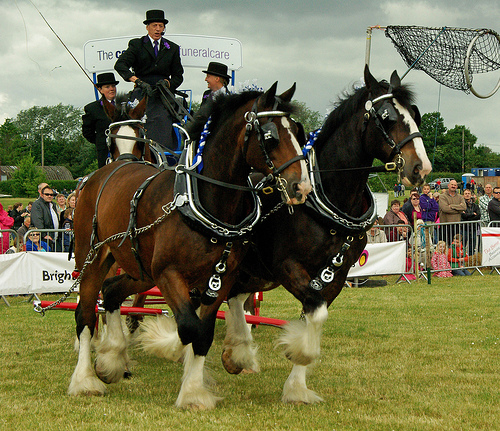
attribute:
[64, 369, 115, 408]
hooves — white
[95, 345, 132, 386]
hooves — white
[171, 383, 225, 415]
hooves — white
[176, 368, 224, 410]
hooves — white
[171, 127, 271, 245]
bridle — black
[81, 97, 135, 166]
suit — black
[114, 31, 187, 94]
suit — black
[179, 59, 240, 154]
person — smiling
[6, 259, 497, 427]
grass — brown, green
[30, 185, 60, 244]
man — wearing sunglasses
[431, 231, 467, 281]
children — small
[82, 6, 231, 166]
three people — wearing black hats